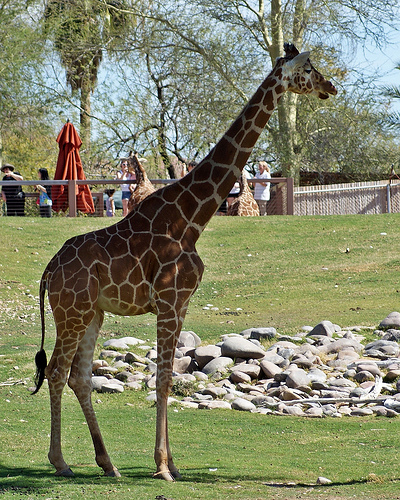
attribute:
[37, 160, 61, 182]
hair — long, black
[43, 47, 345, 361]
giraffe — brown, white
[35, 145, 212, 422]
giraffe — white, brown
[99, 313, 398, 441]
rocks — grey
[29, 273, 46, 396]
tail — black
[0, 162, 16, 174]
hat — safari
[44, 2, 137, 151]
trees — green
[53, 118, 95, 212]
tent cover — orange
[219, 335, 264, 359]
rock — grouped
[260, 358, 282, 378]
rock — grouped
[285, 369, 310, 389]
rock — grouped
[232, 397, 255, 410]
rock — grouped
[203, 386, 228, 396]
rock — grouped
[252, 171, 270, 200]
shirt — long, white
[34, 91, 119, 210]
red umbrella — closed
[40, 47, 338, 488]
giraffe — tan, brown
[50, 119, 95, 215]
umbrella — red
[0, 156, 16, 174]
hat — tan